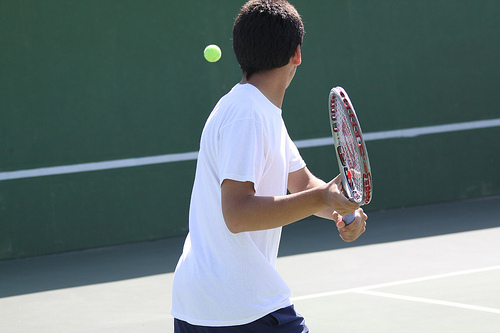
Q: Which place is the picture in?
A: It is at the field.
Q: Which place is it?
A: It is a field.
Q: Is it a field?
A: Yes, it is a field.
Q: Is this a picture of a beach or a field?
A: It is showing a field.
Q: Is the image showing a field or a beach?
A: It is showing a field.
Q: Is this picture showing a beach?
A: No, the picture is showing a field.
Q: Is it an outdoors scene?
A: Yes, it is outdoors.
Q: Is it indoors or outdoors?
A: It is outdoors.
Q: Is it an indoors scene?
A: No, it is outdoors.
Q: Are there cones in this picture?
A: No, there are no cones.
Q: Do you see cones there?
A: No, there are no cones.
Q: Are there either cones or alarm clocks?
A: No, there are no cones or alarm clocks.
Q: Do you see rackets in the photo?
A: Yes, there is a racket.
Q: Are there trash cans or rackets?
A: Yes, there is a racket.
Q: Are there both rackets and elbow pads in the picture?
A: No, there is a racket but no elbow pads.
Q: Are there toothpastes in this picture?
A: No, there are no toothpastes.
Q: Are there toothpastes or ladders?
A: No, there are no toothpastes or ladders.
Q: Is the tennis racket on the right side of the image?
A: Yes, the tennis racket is on the right of the image.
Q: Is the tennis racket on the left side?
A: No, the tennis racket is on the right of the image.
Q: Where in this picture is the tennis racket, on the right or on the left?
A: The tennis racket is on the right of the image.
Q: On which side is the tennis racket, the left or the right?
A: The tennis racket is on the right of the image.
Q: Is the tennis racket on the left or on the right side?
A: The tennis racket is on the right of the image.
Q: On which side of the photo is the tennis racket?
A: The tennis racket is on the right of the image.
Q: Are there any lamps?
A: No, there are no lamps.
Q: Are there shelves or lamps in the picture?
A: No, there are no lamps or shelves.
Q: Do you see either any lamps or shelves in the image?
A: No, there are no lamps or shelves.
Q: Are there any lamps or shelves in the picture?
A: No, there are no lamps or shelves.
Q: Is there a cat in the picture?
A: No, there are no cats.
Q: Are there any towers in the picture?
A: No, there are no towers.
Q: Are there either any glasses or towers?
A: No, there are no towers or glasses.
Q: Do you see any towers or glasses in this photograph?
A: No, there are no towers or glasses.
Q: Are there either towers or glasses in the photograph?
A: No, there are no towers or glasses.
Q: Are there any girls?
A: No, there are no girls.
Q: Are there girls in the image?
A: No, there are no girls.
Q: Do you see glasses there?
A: No, there are no glasses.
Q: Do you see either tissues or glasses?
A: No, there are no glasses or tissues.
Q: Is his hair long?
A: No, the hair is short.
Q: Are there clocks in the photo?
A: No, there are no clocks.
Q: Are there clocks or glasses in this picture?
A: No, there are no clocks or glasses.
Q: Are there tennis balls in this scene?
A: Yes, there is a tennis ball.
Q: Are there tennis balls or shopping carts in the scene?
A: Yes, there is a tennis ball.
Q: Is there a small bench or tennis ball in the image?
A: Yes, there is a small tennis ball.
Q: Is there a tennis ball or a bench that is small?
A: Yes, the tennis ball is small.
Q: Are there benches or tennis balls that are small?
A: Yes, the tennis ball is small.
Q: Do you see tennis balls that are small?
A: Yes, there is a small tennis ball.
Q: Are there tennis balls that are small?
A: Yes, there is a tennis ball that is small.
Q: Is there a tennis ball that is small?
A: Yes, there is a tennis ball that is small.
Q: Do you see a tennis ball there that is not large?
A: Yes, there is a small tennis ball.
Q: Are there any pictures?
A: No, there are no pictures.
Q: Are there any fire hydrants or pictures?
A: No, there are no pictures or fire hydrants.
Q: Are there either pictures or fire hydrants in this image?
A: No, there are no pictures or fire hydrants.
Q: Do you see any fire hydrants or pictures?
A: No, there are no pictures or fire hydrants.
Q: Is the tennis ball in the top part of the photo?
A: Yes, the tennis ball is in the top of the image.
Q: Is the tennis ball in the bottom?
A: No, the tennis ball is in the top of the image.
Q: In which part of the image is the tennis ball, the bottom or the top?
A: The tennis ball is in the top of the image.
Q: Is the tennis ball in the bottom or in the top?
A: The tennis ball is in the top of the image.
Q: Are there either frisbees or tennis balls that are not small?
A: No, there is a tennis ball but it is small.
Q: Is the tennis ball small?
A: Yes, the tennis ball is small.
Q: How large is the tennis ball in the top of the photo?
A: The tennis ball is small.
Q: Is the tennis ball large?
A: No, the tennis ball is small.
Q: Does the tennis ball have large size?
A: No, the tennis ball is small.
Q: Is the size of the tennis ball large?
A: No, the tennis ball is small.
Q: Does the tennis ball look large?
A: No, the tennis ball is small.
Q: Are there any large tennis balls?
A: No, there is a tennis ball but it is small.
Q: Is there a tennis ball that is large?
A: No, there is a tennis ball but it is small.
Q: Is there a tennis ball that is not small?
A: No, there is a tennis ball but it is small.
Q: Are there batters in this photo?
A: No, there are no batters.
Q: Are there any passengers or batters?
A: No, there are no batters or passengers.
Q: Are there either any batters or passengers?
A: No, there are no batters or passengers.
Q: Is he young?
A: Yes, the man is young.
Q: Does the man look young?
A: Yes, the man is young.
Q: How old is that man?
A: The man is young.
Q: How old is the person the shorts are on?
A: The man is young.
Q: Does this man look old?
A: No, the man is young.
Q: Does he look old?
A: No, the man is young.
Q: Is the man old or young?
A: The man is young.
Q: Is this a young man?
A: Yes, this is a young man.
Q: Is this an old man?
A: No, this is a young man.